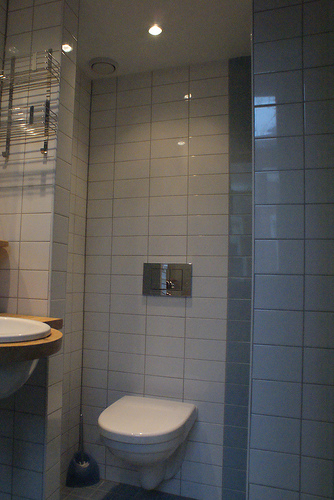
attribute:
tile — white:
[253, 202, 306, 240]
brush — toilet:
[73, 412, 96, 481]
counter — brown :
[0, 306, 67, 400]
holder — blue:
[66, 450, 101, 486]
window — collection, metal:
[140, 257, 195, 300]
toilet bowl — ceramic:
[98, 394, 194, 489]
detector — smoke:
[84, 56, 120, 77]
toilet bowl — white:
[91, 392, 217, 487]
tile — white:
[184, 315, 226, 340]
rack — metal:
[1, 45, 60, 158]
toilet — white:
[94, 387, 206, 487]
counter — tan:
[3, 296, 64, 355]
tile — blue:
[223, 53, 256, 498]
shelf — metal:
[0, 45, 59, 157]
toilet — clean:
[91, 388, 199, 490]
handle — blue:
[76, 410, 87, 457]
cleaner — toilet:
[67, 415, 97, 487]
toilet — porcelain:
[98, 395, 197, 490]